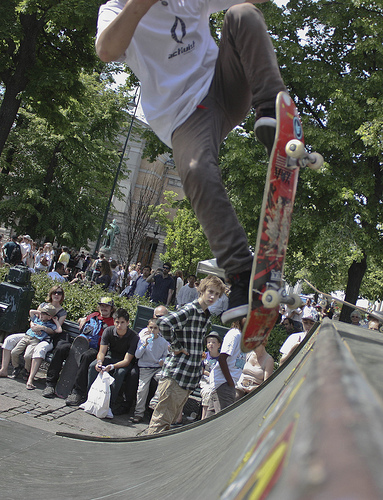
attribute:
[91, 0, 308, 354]
guy — showing tricks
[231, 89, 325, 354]
skateboard — red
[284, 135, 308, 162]
wheel — white, dusty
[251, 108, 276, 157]
shoe — black, dark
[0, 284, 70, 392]
spectator — sitting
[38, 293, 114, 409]
guy — smiling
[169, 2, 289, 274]
pants — tan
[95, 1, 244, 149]
shirt — black, white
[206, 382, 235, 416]
pants — gray, cargo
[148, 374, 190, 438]
pants — tan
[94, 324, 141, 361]
shirt — black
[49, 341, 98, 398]
pants — black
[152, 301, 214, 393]
shirt — plaid, white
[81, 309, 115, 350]
shirt — red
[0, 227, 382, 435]
crowd — reasonably large, sitting around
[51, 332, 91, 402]
skateboard — black, small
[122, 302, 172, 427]
man — nearly hairless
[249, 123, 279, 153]
sole — white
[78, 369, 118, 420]
bag — plastic, white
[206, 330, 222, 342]
hat — black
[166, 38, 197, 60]
text — small